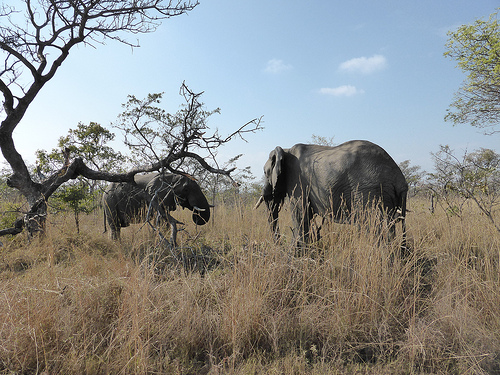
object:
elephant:
[252, 139, 409, 258]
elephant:
[102, 172, 215, 241]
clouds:
[337, 56, 389, 73]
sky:
[199, 0, 440, 79]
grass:
[0, 252, 500, 373]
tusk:
[252, 195, 263, 211]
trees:
[425, 144, 499, 232]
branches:
[42, 79, 267, 262]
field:
[1, 1, 500, 374]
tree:
[0, 0, 264, 263]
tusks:
[193, 206, 205, 211]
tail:
[101, 203, 108, 235]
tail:
[401, 191, 407, 256]